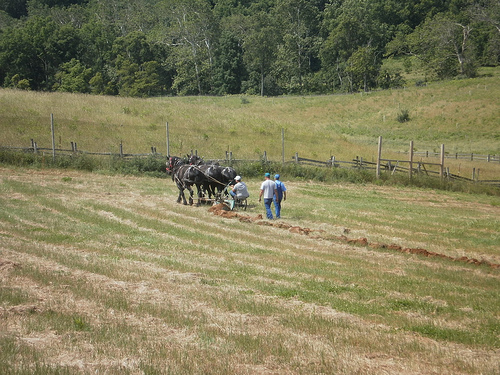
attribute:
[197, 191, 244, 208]
cart — small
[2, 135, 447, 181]
fence — small, wooden, edge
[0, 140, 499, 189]
fences — wooden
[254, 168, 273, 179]
hat — blue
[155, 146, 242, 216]
horse — dark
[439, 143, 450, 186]
fence post — wooden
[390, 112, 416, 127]
green — solitary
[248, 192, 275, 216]
short — white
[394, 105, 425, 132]
shrub — small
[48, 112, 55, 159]
pole — tall, shorter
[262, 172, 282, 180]
caps — blue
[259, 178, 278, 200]
tee shirt — bright, white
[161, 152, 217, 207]
horse — walking, black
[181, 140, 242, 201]
cart — small 